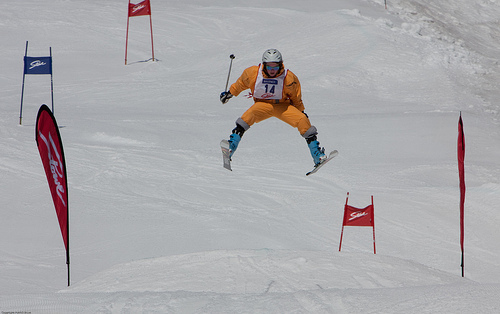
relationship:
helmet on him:
[260, 48, 283, 63] [219, 49, 327, 167]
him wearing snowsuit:
[219, 49, 327, 167] [222, 68, 316, 138]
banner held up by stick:
[334, 188, 382, 256] [364, 188, 382, 255]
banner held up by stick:
[334, 188, 382, 256] [337, 188, 347, 249]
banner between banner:
[20, 41, 56, 125] [20, 41, 56, 125]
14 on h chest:
[250, 70, 288, 98] [243, 68, 290, 102]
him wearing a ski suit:
[219, 49, 327, 167] [239, 72, 301, 122]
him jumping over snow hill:
[219, 49, 327, 167] [1, 110, 497, 312]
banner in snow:
[337, 190, 378, 253] [1, 0, 497, 312]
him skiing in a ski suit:
[219, 49, 327, 167] [228, 60, 314, 140]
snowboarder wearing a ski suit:
[219, 49, 326, 166] [229, 64, 316, 144]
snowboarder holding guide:
[217, 139, 333, 174] [211, 30, 240, 107]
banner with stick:
[337, 190, 378, 253] [367, 193, 377, 253]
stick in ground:
[367, 193, 377, 253] [2, 6, 498, 311]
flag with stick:
[455, 111, 469, 277] [339, 190, 351, 257]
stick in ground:
[339, 190, 351, 257] [2, 6, 498, 311]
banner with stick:
[337, 190, 378, 253] [339, 190, 351, 257]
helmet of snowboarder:
[260, 47, 283, 81] [215, 47, 334, 174]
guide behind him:
[220, 54, 235, 90] [219, 50, 330, 171]